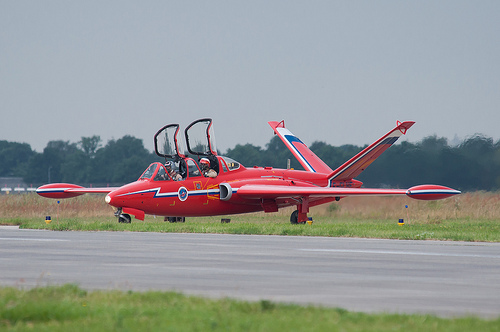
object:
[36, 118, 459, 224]
plane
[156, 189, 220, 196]
line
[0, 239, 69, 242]
airstrip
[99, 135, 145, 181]
tree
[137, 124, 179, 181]
cockpit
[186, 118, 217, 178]
cockpit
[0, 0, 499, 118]
sky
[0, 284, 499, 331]
grass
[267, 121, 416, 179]
tail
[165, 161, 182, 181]
man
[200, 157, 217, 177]
man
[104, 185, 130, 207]
nose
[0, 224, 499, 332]
ground